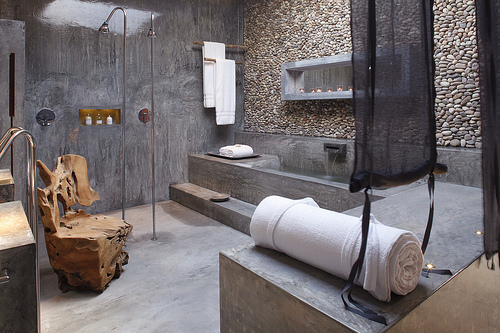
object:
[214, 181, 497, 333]
cupboard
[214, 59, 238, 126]
towel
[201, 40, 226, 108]
towel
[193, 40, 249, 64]
rod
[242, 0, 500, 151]
wall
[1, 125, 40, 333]
railing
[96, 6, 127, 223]
metal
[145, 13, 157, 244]
metal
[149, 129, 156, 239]
metal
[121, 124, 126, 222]
metal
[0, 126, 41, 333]
metal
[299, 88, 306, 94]
candle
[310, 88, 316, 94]
candle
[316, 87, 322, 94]
candle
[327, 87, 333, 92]
candle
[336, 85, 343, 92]
candle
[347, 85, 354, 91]
candle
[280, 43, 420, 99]
shelf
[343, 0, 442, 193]
cloth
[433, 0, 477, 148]
rocks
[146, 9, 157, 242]
shower head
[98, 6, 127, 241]
shower head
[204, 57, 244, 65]
rack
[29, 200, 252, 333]
ground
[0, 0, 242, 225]
wall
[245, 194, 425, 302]
white towel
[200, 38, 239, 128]
green wood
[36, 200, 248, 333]
gray floor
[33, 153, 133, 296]
wood chair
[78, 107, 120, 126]
shelf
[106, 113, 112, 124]
bottle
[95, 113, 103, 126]
bottle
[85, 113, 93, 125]
bottle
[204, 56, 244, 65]
rack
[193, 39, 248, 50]
rack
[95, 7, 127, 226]
shower head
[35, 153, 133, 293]
chair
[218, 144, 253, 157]
towel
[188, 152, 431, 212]
bath tub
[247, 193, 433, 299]
mat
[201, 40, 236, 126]
towel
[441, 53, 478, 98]
pebbles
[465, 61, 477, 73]
stones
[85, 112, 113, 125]
toiletries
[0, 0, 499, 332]
bathroom